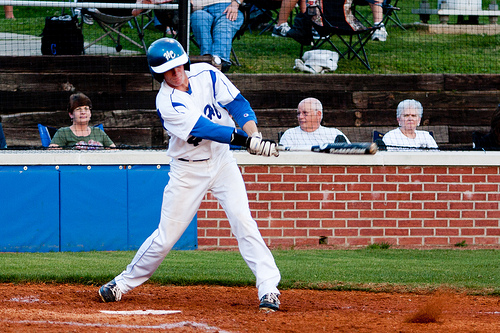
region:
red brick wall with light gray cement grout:
[308, 176, 429, 245]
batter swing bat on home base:
[86, 35, 386, 317]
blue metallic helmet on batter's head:
[141, 34, 190, 89]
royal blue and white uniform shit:
[151, 78, 256, 173]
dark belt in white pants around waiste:
[168, 147, 225, 172]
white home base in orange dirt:
[81, 295, 192, 325]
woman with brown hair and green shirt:
[38, 84, 125, 160]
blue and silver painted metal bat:
[259, 135, 391, 167]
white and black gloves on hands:
[242, 133, 285, 162]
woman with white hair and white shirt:
[376, 95, 448, 165]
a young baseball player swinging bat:
[97, 37, 374, 309]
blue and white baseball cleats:
[97, 274, 282, 311]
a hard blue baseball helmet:
[146, 34, 194, 86]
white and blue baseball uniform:
[94, 63, 281, 301]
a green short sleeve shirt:
[49, 125, 114, 161]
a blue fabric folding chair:
[34, 120, 103, 147]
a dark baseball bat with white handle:
[279, 140, 378, 157]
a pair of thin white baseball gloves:
[244, 133, 278, 159]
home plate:
[100, 304, 180, 315]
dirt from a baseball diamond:
[3, 278, 497, 330]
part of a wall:
[406, 226, 414, 236]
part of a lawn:
[348, 258, 353, 263]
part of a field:
[351, 235, 361, 268]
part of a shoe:
[269, 300, 273, 303]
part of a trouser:
[256, 256, 264, 263]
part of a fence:
[378, 56, 390, 71]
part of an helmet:
[156, 50, 161, 58]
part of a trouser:
[158, 228, 164, 245]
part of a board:
[78, 201, 85, 209]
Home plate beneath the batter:
[99, 302, 177, 317]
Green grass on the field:
[6, 245, 498, 297]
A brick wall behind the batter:
[196, 154, 494, 244]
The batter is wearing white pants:
[114, 157, 285, 298]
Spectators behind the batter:
[56, 95, 440, 150]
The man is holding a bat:
[260, 136, 386, 158]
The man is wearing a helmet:
[145, 33, 190, 70]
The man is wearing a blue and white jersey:
[145, 62, 259, 149]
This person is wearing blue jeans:
[194, 4, 240, 56]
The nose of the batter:
[170, 68, 180, 80]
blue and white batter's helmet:
[135, 27, 206, 82]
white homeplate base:
[98, 298, 187, 331]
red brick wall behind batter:
[323, 160, 471, 271]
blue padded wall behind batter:
[5, 168, 110, 250]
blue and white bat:
[280, 136, 388, 160]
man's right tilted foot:
[85, 255, 142, 316]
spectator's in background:
[287, 95, 449, 148]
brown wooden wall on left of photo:
[8, 56, 66, 108]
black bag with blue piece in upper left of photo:
[28, 10, 106, 70]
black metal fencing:
[426, 17, 498, 72]